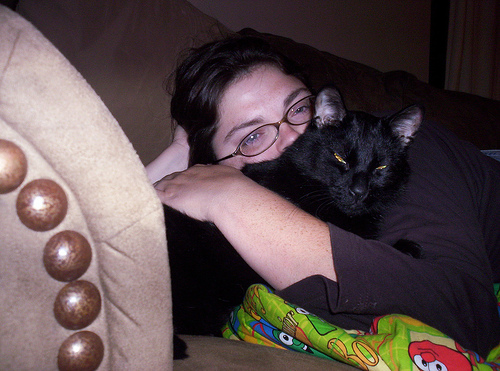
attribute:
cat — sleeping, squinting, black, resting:
[160, 85, 423, 358]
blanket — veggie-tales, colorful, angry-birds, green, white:
[223, 281, 499, 370]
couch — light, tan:
[0, 2, 216, 369]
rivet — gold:
[16, 178, 68, 234]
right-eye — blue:
[241, 131, 269, 147]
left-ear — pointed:
[385, 104, 423, 148]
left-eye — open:
[292, 104, 311, 115]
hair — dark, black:
[171, 32, 310, 167]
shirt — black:
[277, 113, 499, 364]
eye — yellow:
[331, 153, 346, 166]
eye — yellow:
[374, 163, 388, 171]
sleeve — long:
[277, 223, 499, 355]